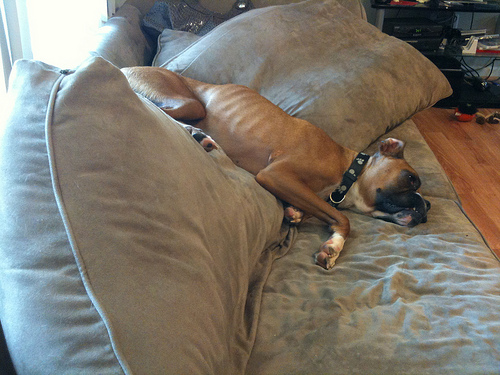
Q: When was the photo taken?
A: Daytime.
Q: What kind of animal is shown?
A: Dog.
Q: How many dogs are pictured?
A: One.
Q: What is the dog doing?
A: Lying.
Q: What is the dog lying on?
A: Couch.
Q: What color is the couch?
A: Brown.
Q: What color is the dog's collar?
A: Black.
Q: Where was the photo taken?
A: In the living room of a home.